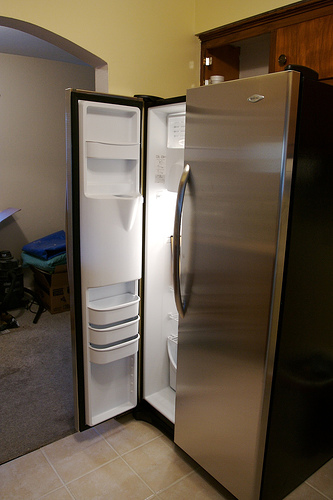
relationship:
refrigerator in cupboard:
[62, 69, 297, 493] [192, 3, 332, 82]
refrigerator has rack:
[62, 69, 297, 493] [85, 125, 140, 364]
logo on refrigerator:
[246, 93, 265, 102] [62, 69, 297, 493]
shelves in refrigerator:
[81, 281, 141, 365] [62, 69, 297, 493]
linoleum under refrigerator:
[0, 420, 317, 497] [62, 69, 297, 493]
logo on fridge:
[246, 93, 265, 102] [63, 68, 300, 498]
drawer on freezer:
[160, 338, 181, 393] [64, 81, 185, 431]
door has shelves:
[60, 82, 147, 439] [79, 98, 142, 307]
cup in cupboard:
[208, 74, 225, 84] [198, 26, 327, 77]